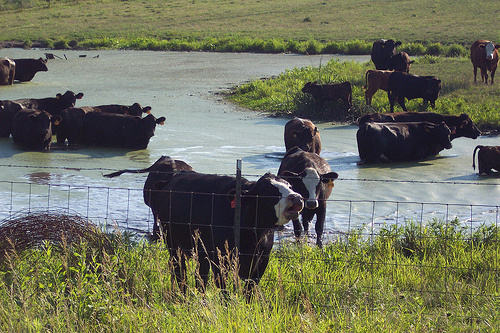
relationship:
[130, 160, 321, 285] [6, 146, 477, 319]
cow at fence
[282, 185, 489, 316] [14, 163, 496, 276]
wire running along fence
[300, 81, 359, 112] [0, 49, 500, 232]
calf standing at edge of water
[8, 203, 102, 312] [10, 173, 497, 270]
wire by fence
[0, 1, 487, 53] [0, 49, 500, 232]
field across water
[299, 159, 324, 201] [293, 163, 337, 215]
stripe on face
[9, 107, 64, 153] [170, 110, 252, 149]
cattle in water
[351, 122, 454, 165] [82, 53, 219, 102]
cow in water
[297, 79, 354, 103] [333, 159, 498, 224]
calf by water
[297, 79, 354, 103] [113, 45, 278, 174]
calf by water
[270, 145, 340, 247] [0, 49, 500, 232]
cow in water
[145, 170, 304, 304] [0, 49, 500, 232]
cow in water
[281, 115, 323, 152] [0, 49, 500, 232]
cattle in water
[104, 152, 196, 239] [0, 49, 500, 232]
cow in water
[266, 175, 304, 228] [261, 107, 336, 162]
face of cow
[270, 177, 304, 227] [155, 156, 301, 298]
face of cow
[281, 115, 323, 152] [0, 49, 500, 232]
cattle inside water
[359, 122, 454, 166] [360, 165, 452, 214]
cow bathing in water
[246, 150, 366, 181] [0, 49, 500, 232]
shadow in water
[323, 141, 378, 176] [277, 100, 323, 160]
shadow of cow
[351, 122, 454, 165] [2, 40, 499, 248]
cow in water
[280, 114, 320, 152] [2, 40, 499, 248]
cattle in water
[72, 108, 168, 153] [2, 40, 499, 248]
cattle in water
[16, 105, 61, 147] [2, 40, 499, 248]
cattle in water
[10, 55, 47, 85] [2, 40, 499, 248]
cattle in water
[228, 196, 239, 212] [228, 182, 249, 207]
tag on ear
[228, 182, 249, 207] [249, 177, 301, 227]
ear of cow